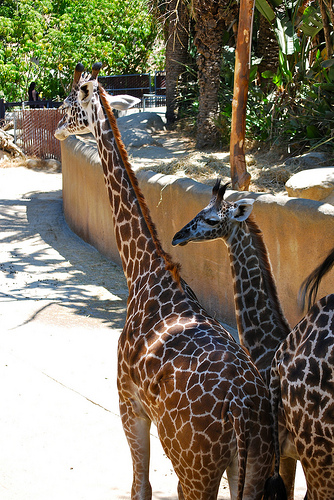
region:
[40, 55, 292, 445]
giraffes beside the wall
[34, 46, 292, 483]
the giraffes are spotted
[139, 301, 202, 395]
the spots are brown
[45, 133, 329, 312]
the wall is concrete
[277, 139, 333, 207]
stone above the wall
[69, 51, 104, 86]
ossicones on the head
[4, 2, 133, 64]
trees with green leaves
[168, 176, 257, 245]
head of the giraffe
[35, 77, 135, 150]
head of the giraffe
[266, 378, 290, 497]
tail of the giraffe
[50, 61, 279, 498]
tan giraffe with brown spots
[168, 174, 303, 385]
tan giraffe with brown spots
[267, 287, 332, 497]
tan giraffe with brown spots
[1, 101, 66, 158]
metal chain link fence with brown lattice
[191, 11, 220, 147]
brown trunk of a palm tree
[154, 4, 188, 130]
brown trunk of a palm tree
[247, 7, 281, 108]
brown trunk of a palm tree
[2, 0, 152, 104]
tall leafy green trees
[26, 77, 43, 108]
person standing near the trees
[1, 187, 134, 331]
shadows cast by palm trees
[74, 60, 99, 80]
The horns of the giraffe on the left.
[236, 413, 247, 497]
The tail of the giraffe on the left.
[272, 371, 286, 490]
The tail of the giraffe on the right.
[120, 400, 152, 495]
The front leg of the giraffe on the left.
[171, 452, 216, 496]
The back left leg of the giraffe on the left.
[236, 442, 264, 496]
The back right leg of the giraffe on the right.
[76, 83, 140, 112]
The ears of the giraffe on the left.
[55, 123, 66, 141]
The nose and mouth area of the giraffe on the left.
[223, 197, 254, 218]
The ears of the giraffe on the right.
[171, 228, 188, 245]
The nose and mouth area of the giraffe on the right.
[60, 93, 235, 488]
tall giraffe in zoo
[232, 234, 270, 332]
tall giraffe in zoo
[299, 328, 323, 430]
tall giraffe in zoo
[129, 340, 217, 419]
brown spots on giraffe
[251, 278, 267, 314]
brown spots on giraffe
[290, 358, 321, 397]
brown spots on giraffe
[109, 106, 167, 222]
red mane on giraffe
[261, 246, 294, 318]
red mane on giraffe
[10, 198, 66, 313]
shadow of tree on ground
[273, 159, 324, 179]
large rocks on wall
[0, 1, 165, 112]
Green trees in the woods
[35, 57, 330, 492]
Three giraffes standing next to each other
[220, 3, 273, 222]
Telephone pole made out of wood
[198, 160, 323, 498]
Baby giraffe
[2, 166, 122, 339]
Shadows of the trees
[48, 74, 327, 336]
Wall made out of cement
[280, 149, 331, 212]
Rock on the upper side of the wall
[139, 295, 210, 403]
Spots on side of one giraffe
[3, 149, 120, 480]
Ground where giraffes are walking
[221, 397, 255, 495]
Tail of a giraffe